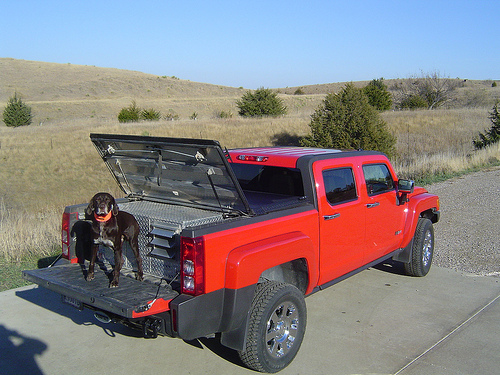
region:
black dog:
[73, 182, 152, 273]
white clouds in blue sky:
[75, 11, 117, 34]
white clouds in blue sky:
[411, 21, 454, 59]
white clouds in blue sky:
[318, 19, 356, 57]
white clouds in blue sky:
[161, 19, 229, 61]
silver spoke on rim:
[281, 308, 288, 317]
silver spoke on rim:
[288, 308, 299, 321]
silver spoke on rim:
[287, 325, 302, 339]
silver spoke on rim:
[278, 338, 289, 353]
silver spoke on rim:
[271, 343, 281, 357]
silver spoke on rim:
[266, 328, 276, 345]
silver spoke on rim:
[273, 311, 280, 324]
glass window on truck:
[322, 171, 357, 201]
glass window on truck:
[359, 163, 394, 189]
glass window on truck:
[232, 162, 305, 197]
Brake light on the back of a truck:
[237, 153, 269, 162]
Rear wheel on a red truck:
[238, 280, 306, 372]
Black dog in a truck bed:
[85, 192, 144, 287]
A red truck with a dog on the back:
[23, 133, 441, 373]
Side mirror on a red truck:
[394, 177, 414, 194]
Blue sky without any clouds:
[1, 0, 499, 91]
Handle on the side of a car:
[323, 211, 340, 220]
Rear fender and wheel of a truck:
[228, 231, 315, 373]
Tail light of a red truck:
[176, 235, 205, 295]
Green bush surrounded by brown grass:
[6, 92, 33, 129]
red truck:
[175, 139, 439, 327]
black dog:
[58, 191, 143, 288]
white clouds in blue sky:
[324, 22, 395, 53]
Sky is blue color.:
[111, 15, 382, 57]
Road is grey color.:
[305, 294, 481, 371]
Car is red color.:
[186, 117, 391, 281]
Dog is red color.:
[58, 197, 151, 283]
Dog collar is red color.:
[90, 205, 127, 227]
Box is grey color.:
[125, 199, 215, 262]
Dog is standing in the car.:
[18, 165, 156, 276]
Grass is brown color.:
[6, 141, 75, 220]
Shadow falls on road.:
[3, 272, 99, 374]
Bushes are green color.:
[306, 83, 392, 155]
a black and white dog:
[78, 177, 150, 302]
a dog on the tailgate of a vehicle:
[74, 187, 155, 301]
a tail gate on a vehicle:
[27, 255, 172, 325]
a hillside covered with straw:
[16, 52, 188, 108]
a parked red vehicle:
[30, 112, 462, 359]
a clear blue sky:
[109, 17, 359, 63]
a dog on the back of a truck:
[68, 177, 153, 305]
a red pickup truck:
[28, 135, 440, 372]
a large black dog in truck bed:
[80, 192, 147, 288]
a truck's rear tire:
[236, 282, 306, 372]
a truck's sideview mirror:
[396, 177, 413, 196]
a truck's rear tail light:
[182, 238, 203, 295]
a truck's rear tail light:
[59, 214, 69, 257]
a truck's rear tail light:
[237, 152, 265, 162]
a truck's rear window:
[231, 161, 301, 198]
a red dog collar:
[91, 211, 113, 222]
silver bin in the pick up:
[88, 182, 209, 282]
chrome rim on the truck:
[268, 300, 304, 362]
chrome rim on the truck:
[419, 227, 435, 267]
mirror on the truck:
[390, 178, 412, 198]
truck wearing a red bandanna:
[86, 210, 111, 222]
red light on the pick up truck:
[176, 236, 207, 294]